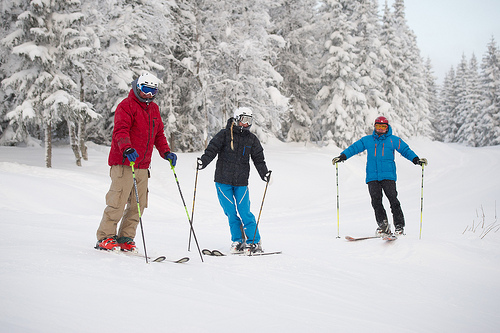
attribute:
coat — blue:
[340, 131, 415, 182]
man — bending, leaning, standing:
[96, 73, 174, 252]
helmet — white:
[139, 71, 161, 90]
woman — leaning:
[195, 109, 273, 254]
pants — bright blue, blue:
[215, 181, 260, 244]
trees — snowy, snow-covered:
[3, 6, 498, 141]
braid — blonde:
[225, 122, 235, 149]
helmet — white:
[235, 109, 254, 121]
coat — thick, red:
[109, 89, 171, 163]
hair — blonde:
[229, 123, 236, 150]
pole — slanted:
[125, 155, 147, 261]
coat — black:
[201, 120, 271, 186]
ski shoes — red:
[100, 234, 139, 250]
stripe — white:
[217, 184, 249, 201]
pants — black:
[369, 178, 405, 226]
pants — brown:
[100, 164, 149, 240]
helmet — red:
[375, 118, 387, 124]